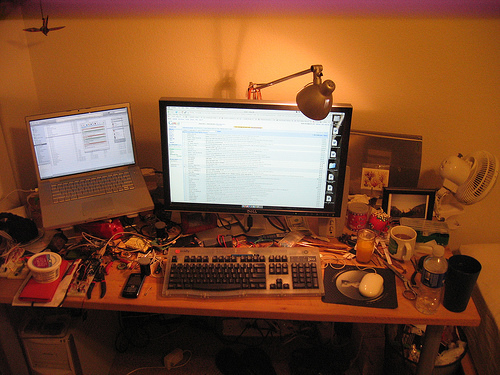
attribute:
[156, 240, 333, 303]
keyboard — mechanical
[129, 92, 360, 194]
monitor — silver and black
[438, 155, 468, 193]
fan — oscillating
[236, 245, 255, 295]
keys — black